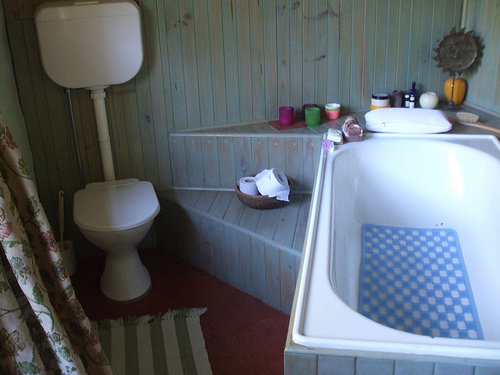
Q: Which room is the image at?
A: It is at the bathroom.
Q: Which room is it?
A: It is a bathroom.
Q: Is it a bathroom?
A: Yes, it is a bathroom.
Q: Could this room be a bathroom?
A: Yes, it is a bathroom.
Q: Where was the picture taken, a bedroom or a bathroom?
A: It was taken at a bathroom.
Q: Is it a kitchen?
A: No, it is a bathroom.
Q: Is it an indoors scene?
A: Yes, it is indoors.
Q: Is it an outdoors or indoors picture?
A: It is indoors.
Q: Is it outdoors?
A: No, it is indoors.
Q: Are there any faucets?
A: No, there are no faucets.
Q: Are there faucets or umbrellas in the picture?
A: No, there are no faucets or umbrellas.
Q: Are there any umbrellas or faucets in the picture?
A: No, there are no faucets or umbrellas.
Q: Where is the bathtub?
A: The bathtub is in the bathroom.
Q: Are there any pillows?
A: Yes, there is a pillow.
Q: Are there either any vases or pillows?
A: Yes, there is a pillow.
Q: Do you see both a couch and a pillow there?
A: No, there is a pillow but no couches.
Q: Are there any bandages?
A: No, there are no bandages.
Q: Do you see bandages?
A: No, there are no bandages.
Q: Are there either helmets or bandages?
A: No, there are no bandages or helmets.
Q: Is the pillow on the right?
A: Yes, the pillow is on the right of the image.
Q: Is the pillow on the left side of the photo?
A: No, the pillow is on the right of the image.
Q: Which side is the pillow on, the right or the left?
A: The pillow is on the right of the image.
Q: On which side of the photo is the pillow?
A: The pillow is on the right of the image.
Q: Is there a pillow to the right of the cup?
A: Yes, there is a pillow to the right of the cup.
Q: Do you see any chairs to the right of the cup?
A: No, there is a pillow to the right of the cup.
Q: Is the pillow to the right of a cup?
A: Yes, the pillow is to the right of a cup.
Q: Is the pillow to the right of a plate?
A: No, the pillow is to the right of a cup.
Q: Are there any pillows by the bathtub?
A: Yes, there is a pillow by the bathtub.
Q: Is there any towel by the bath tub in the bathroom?
A: No, there is a pillow by the tub.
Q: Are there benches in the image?
A: No, there are no benches.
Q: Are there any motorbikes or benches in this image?
A: No, there are no benches or motorbikes.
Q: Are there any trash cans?
A: No, there are no trash cans.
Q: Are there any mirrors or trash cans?
A: No, there are no trash cans or mirrors.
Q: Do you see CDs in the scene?
A: No, there are no cds.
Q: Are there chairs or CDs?
A: No, there are no CDs or chairs.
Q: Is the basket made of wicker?
A: Yes, the basket is made of wicker.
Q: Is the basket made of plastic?
A: No, the basket is made of wicker.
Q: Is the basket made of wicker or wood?
A: The basket is made of wicker.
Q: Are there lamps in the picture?
A: No, there are no lamps.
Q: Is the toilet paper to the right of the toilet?
A: Yes, the toilet paper is to the right of the toilet.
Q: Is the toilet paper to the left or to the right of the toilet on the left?
A: The toilet paper is to the right of the toilet.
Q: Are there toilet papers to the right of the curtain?
A: Yes, there is a toilet paper to the right of the curtain.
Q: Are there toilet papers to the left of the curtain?
A: No, the toilet paper is to the right of the curtain.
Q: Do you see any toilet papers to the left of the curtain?
A: No, the toilet paper is to the right of the curtain.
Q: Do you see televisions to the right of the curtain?
A: No, there is a toilet paper to the right of the curtain.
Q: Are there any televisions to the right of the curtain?
A: No, there is a toilet paper to the right of the curtain.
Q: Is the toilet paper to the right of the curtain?
A: Yes, the toilet paper is to the right of the curtain.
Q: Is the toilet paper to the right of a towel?
A: No, the toilet paper is to the right of the curtain.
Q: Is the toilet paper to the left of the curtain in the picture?
A: No, the toilet paper is to the right of the curtain.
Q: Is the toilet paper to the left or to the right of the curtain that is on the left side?
A: The toilet paper is to the right of the curtain.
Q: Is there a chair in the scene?
A: No, there are no chairs.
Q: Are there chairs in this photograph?
A: No, there are no chairs.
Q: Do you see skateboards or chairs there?
A: No, there are no chairs or skateboards.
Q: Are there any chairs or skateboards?
A: No, there are no chairs or skateboards.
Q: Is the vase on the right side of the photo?
A: Yes, the vase is on the right of the image.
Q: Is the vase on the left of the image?
A: No, the vase is on the right of the image.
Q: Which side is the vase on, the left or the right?
A: The vase is on the right of the image.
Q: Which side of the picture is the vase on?
A: The vase is on the right of the image.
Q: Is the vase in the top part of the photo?
A: Yes, the vase is in the top of the image.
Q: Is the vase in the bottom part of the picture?
A: No, the vase is in the top of the image.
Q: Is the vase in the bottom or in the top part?
A: The vase is in the top of the image.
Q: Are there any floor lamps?
A: No, there are no floor lamps.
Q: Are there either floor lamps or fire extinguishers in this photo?
A: No, there are no floor lamps or fire extinguishers.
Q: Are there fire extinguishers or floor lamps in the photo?
A: No, there are no floor lamps or fire extinguishers.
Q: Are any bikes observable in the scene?
A: No, there are no bikes.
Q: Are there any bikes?
A: No, there are no bikes.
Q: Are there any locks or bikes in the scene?
A: No, there are no bikes or locks.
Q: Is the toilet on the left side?
A: Yes, the toilet is on the left of the image.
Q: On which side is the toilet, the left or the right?
A: The toilet is on the left of the image.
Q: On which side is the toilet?
A: The toilet is on the left of the image.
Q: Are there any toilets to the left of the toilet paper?
A: Yes, there is a toilet to the left of the toilet paper.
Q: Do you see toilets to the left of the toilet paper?
A: Yes, there is a toilet to the left of the toilet paper.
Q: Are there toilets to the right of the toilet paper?
A: No, the toilet is to the left of the toilet paper.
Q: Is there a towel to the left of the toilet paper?
A: No, there is a toilet to the left of the toilet paper.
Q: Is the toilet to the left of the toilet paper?
A: Yes, the toilet is to the left of the toilet paper.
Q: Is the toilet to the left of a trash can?
A: No, the toilet is to the left of the toilet paper.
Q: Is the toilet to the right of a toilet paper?
A: No, the toilet is to the left of a toilet paper.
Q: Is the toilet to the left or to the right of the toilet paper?
A: The toilet is to the left of the toilet paper.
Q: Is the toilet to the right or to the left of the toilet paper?
A: The toilet is to the left of the toilet paper.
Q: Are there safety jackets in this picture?
A: No, there are no safety jackets.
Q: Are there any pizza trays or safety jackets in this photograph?
A: No, there are no safety jackets or pizza trays.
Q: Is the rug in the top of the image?
A: No, the rug is in the bottom of the image.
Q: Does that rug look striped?
A: Yes, the rug is striped.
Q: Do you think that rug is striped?
A: Yes, the rug is striped.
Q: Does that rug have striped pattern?
A: Yes, the rug is striped.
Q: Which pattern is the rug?
A: The rug is striped.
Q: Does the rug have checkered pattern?
A: No, the rug is striped.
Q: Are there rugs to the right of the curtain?
A: Yes, there is a rug to the right of the curtain.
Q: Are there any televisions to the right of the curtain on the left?
A: No, there is a rug to the right of the curtain.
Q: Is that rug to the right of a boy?
A: No, the rug is to the right of a curtain.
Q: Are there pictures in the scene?
A: No, there are no pictures.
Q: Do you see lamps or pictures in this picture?
A: No, there are no pictures or lamps.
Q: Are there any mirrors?
A: No, there are no mirrors.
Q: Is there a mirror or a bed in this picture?
A: No, there are no mirrors or beds.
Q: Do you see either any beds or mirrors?
A: No, there are no mirrors or beds.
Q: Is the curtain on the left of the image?
A: Yes, the curtain is on the left of the image.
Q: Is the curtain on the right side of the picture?
A: No, the curtain is on the left of the image.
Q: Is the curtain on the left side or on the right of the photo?
A: The curtain is on the left of the image.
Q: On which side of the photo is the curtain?
A: The curtain is on the left of the image.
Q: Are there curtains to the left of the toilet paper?
A: Yes, there is a curtain to the left of the toilet paper.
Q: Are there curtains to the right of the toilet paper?
A: No, the curtain is to the left of the toilet paper.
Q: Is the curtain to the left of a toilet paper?
A: Yes, the curtain is to the left of a toilet paper.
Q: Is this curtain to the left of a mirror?
A: No, the curtain is to the left of a toilet paper.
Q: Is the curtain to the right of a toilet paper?
A: No, the curtain is to the left of a toilet paper.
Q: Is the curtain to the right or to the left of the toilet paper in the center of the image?
A: The curtain is to the left of the toilet paper.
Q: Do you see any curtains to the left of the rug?
A: Yes, there is a curtain to the left of the rug.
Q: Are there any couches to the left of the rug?
A: No, there is a curtain to the left of the rug.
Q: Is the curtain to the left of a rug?
A: Yes, the curtain is to the left of a rug.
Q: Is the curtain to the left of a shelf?
A: No, the curtain is to the left of a rug.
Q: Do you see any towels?
A: No, there are no towels.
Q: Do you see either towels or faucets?
A: No, there are no towels or faucets.